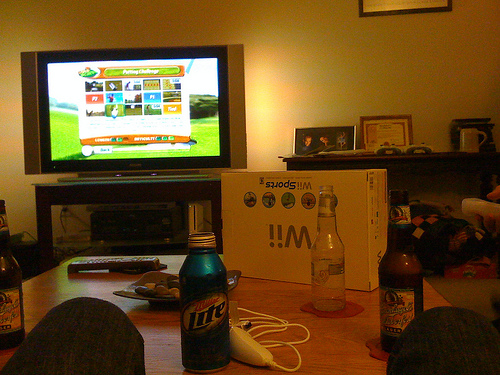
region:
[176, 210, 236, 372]
miller lite beer on table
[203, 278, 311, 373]
wii controller on table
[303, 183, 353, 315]
empty glass bottle on table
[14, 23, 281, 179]
flat screen television on table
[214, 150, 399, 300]
wii box on table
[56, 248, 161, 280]
remote control on table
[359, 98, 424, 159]
frame on side table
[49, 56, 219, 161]
bright screen on television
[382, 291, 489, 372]
person's knee by table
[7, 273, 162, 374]
person's knee by table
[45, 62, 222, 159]
wii game on the screen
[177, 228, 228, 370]
can of beer on the table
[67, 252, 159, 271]
remote on the table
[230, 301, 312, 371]
wii remote on the table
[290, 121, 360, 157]
picture on the mantel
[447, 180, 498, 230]
wii remote in the hand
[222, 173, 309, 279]
wii console game box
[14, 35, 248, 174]
tv on the stand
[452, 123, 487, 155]
mug on the shelf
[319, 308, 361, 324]
red coaster on the table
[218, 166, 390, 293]
cardboard box with the word Wii on it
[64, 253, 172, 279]
remote control device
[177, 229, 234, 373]
glass bottle of Miller Lite beer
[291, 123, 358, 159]
framed photograph of two people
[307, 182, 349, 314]
empty bottle of beer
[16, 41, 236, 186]
illuminated television screen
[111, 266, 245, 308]
ashtray filled with snacks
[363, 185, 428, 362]
brown beer bottle sitting on a coaster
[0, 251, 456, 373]
wood grained table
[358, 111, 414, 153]
framed certificat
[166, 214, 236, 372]
this is a bottle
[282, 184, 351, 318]
this is a bottle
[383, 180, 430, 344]
this is a bottle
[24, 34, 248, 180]
this is a screen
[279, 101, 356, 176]
this is a picture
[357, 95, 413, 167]
this is a picture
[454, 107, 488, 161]
this is a cup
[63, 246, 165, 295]
this is a keboard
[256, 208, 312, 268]
this is a word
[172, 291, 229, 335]
this is a word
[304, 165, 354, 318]
The bottle is clear.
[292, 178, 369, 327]
The bottle is sitting on a coaster.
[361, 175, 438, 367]
The bottle is almost full.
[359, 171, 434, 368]
The bottle is brown.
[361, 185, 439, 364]
The bottle is sitting on a coaster.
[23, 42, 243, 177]
The television is a flat screen.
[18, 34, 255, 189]
The television is on.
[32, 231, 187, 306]
A controller is sitting on the table.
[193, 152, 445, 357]
A Wii bos is sitting on the table.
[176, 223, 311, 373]
A game controller is next to the Miller Lite bottle.